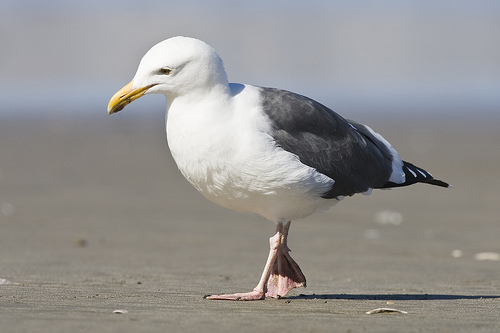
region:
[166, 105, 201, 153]
part of a chest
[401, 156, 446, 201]
part of a tail wing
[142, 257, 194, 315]
part of a floor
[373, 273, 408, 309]
part of a shade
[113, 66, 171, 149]
Bird has yellow beak.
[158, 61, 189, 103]
Bird has light colored eye.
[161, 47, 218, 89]
Bird has white head.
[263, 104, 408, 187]
Bird has gray feathers.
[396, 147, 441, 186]
Bird has black tail feathers.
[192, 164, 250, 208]
Bird has white chest.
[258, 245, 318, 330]
Bird has orange feet.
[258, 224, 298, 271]
Bird has orange legs.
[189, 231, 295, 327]
Bird is standing on the sand.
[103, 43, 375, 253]
Bird is white, gray and black.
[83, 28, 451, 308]
seagull standing on sand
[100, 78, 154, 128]
yellow beak on bird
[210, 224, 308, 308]
pink legs on bird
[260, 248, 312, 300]
webbed foot of bird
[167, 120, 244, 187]
white feathers on chest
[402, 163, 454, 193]
black feathers on tail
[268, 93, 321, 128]
gray feathers on back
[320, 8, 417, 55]
gray of daytime sky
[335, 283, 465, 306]
bird shadow on sand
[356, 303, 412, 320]
broken shell in sand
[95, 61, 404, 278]
this is a bird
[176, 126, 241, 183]
ther bird white in color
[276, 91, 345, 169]
this is the wing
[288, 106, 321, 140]
the wiong is black in color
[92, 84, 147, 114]
this is the beak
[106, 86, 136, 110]
the beak is yellow in color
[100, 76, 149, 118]
the beak is short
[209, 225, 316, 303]
this is the leg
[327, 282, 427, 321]
this is the ground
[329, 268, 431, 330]
the ground is bare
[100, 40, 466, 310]
A gray and white bird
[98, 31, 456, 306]
A gray and white seagull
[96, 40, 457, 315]
A seagull standing in sand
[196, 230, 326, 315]
A gull's webbed feet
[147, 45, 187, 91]
A bird's eye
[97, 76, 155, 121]
A yellow seagull bill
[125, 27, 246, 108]
A bird's head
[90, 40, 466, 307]
An adult herring gull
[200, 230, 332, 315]
Pink webbed feet of a seagull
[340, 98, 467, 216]
The tail end of a seagull